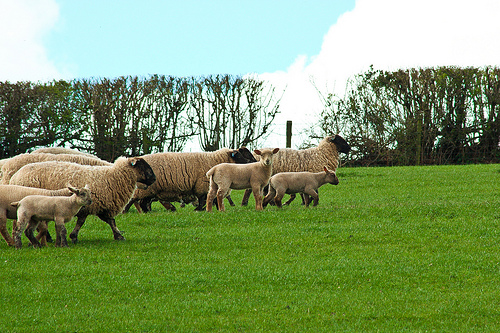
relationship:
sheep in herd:
[269, 167, 339, 211] [1, 132, 355, 247]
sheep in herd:
[205, 149, 278, 210] [1, 132, 355, 247]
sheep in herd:
[12, 186, 91, 245] [1, 132, 355, 247]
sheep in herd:
[271, 135, 349, 172] [1, 132, 355, 247]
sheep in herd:
[10, 159, 157, 241] [1, 132, 355, 247]